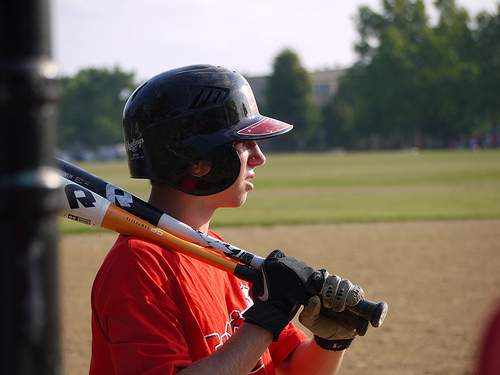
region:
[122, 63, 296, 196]
The navy blue and red helmet.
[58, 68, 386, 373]
A young male holding two bats.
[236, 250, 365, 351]
The black and grey gloves.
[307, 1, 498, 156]
A patch of trees.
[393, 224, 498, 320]
The brown dirt ground.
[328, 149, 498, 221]
The neatly mowed grassy field.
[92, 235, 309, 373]
The orange uniform top.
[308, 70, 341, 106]
The tan-colored building.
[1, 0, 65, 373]
The tall black pole.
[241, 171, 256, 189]
The baseball players open mouth.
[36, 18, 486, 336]
baseball player holding two bats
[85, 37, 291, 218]
baseball player wearing a black helmet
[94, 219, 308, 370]
baseball player wearing a red t-shirt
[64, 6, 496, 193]
trees in the background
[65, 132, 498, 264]
soil and grass turf in the background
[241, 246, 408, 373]
baseball gripping gloves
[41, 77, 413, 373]
orange white and black baseball bat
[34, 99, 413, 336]
black and white baseball bat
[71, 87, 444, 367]
boy holding bats with both hands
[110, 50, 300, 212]
black baseball helmet with a red bibb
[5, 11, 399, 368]
it is baseball game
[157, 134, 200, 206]
shadow is cast on the boy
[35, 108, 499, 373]
it is a daytime scene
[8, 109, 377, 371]
it is an outdoor scene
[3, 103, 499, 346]
it is in a baseball field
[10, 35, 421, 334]
it is sunny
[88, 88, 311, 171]
the boy has a black helmet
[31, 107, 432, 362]
the boy is holding bats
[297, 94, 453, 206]
the plants are green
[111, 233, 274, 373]
the boy has a red shirt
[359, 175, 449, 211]
the grass is green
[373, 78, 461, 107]
the trees are green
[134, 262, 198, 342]
the top is red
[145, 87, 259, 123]
the helmet is black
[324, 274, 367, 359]
the glove is grey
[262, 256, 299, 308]
the glove is black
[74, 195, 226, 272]
the bat is orange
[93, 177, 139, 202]
the bat is black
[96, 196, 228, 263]
the bats are made of wood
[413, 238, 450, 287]
the ground is brown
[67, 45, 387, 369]
He is holding two bats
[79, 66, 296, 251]
He is wearing a helmet for safety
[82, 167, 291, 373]
His jersey is orange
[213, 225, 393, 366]
His gloves are for batting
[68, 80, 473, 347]
He is playing baseball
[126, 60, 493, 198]
There are trees in the background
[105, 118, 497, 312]
The field is grass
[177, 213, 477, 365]
The diamond is dirt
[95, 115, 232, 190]
The helmet brand is Rawlings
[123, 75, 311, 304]
His helmet is black